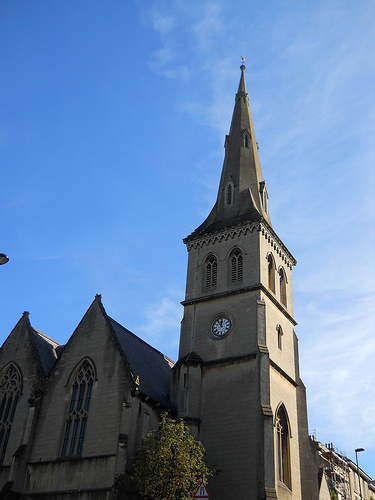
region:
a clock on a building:
[181, 299, 281, 357]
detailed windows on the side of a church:
[50, 336, 128, 482]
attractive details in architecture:
[2, 284, 153, 498]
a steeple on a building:
[170, 49, 309, 334]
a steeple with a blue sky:
[159, 34, 321, 246]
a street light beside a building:
[329, 429, 374, 497]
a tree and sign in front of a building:
[109, 388, 225, 499]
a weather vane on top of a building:
[227, 43, 262, 101]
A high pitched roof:
[3, 285, 199, 420]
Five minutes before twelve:
[185, 300, 275, 365]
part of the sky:
[65, 31, 116, 71]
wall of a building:
[208, 398, 243, 428]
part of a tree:
[148, 437, 194, 475]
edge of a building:
[109, 409, 131, 439]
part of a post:
[191, 476, 206, 496]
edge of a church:
[252, 424, 274, 462]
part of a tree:
[167, 464, 189, 487]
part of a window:
[60, 407, 90, 438]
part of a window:
[262, 425, 295, 473]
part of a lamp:
[338, 430, 366, 456]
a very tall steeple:
[211, 48, 274, 215]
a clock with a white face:
[181, 294, 271, 366]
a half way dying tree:
[120, 400, 250, 490]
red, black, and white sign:
[182, 476, 217, 496]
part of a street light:
[0, 241, 21, 287]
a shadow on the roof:
[105, 303, 178, 386]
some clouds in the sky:
[108, 228, 256, 348]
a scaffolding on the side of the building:
[304, 432, 355, 492]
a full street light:
[351, 440, 370, 497]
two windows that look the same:
[189, 225, 256, 291]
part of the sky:
[95, 25, 143, 56]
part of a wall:
[222, 401, 266, 436]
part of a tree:
[157, 430, 180, 456]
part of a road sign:
[187, 471, 217, 491]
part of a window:
[275, 432, 290, 457]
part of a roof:
[130, 340, 147, 350]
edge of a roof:
[131, 377, 167, 404]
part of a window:
[62, 373, 108, 436]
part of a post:
[353, 462, 370, 488]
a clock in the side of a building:
[208, 311, 233, 339]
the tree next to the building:
[125, 418, 212, 497]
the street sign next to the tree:
[192, 481, 211, 498]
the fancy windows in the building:
[57, 360, 87, 452]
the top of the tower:
[185, 54, 304, 251]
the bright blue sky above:
[0, 3, 193, 318]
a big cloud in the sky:
[270, 121, 373, 442]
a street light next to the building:
[355, 445, 372, 498]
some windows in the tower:
[198, 242, 244, 288]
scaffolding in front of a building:
[320, 440, 348, 498]